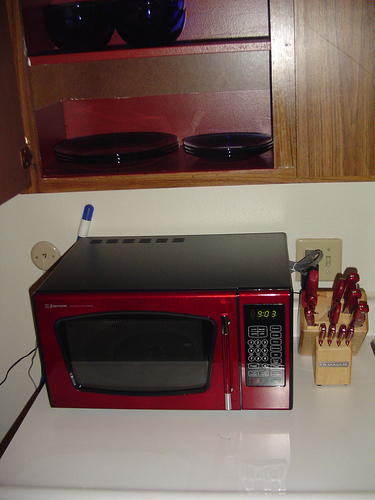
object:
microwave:
[26, 230, 295, 413]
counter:
[2, 339, 375, 495]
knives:
[317, 321, 327, 346]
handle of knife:
[351, 301, 370, 326]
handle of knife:
[329, 298, 342, 328]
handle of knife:
[332, 275, 347, 308]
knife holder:
[312, 332, 354, 387]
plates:
[52, 130, 181, 171]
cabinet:
[0, 1, 375, 181]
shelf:
[30, 169, 295, 194]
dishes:
[113, 0, 187, 48]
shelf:
[21, 31, 269, 66]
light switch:
[292, 236, 343, 284]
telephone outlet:
[29, 236, 61, 272]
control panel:
[248, 323, 282, 379]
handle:
[75, 201, 94, 241]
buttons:
[268, 324, 281, 340]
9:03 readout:
[256, 309, 277, 319]